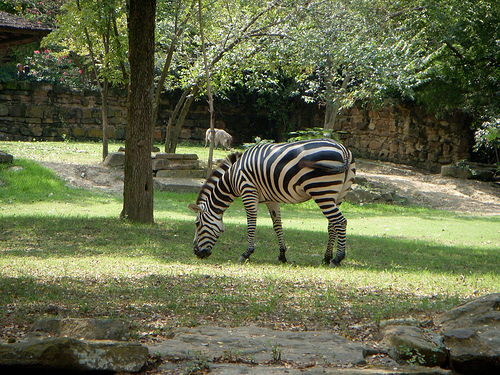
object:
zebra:
[187, 134, 366, 268]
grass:
[0, 136, 499, 373]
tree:
[118, 0, 160, 226]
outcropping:
[154, 148, 202, 177]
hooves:
[274, 252, 291, 265]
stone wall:
[0, 30, 237, 147]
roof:
[0, 10, 57, 38]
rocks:
[145, 326, 390, 374]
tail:
[295, 156, 354, 174]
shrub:
[390, 0, 500, 169]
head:
[184, 203, 228, 261]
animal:
[200, 127, 233, 152]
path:
[350, 159, 500, 214]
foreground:
[0, 134, 499, 373]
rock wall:
[334, 103, 471, 169]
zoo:
[0, 0, 499, 374]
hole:
[141, 180, 151, 192]